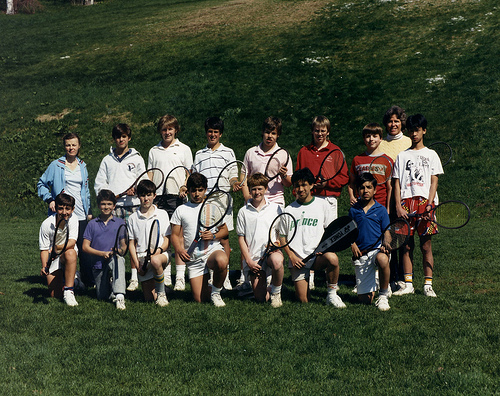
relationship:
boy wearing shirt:
[86, 188, 131, 310] [87, 215, 129, 248]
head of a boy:
[136, 179, 157, 208] [124, 178, 172, 306]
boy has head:
[258, 100, 286, 165] [259, 113, 283, 149]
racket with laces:
[251, 213, 297, 278] [209, 206, 219, 216]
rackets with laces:
[177, 160, 249, 261] [209, 206, 219, 216]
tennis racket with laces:
[48, 211, 68, 272] [209, 206, 219, 216]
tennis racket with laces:
[315, 147, 347, 184] [209, 206, 219, 216]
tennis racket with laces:
[264, 142, 289, 179] [209, 206, 219, 216]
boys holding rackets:
[36, 112, 446, 309] [177, 158, 244, 263]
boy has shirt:
[344, 171, 395, 313] [345, 199, 393, 254]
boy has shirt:
[292, 117, 343, 219] [293, 141, 348, 189]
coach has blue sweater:
[25, 120, 99, 237] [34, 155, 94, 215]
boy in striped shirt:
[196, 117, 236, 215] [193, 143, 238, 187]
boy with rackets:
[196, 117, 236, 215] [177, 160, 249, 261]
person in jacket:
[35, 131, 90, 291] [36, 156, 91, 218]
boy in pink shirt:
[239, 117, 294, 206] [227, 119, 297, 189]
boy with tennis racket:
[239, 117, 294, 206] [243, 143, 305, 205]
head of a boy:
[55, 193, 76, 220] [38, 193, 79, 307]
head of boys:
[174, 171, 210, 202] [168, 171, 229, 309]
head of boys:
[186, 172, 209, 203] [168, 171, 229, 309]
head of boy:
[284, 163, 324, 206] [279, 167, 347, 309]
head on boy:
[157, 114, 180, 139] [140, 116, 195, 202]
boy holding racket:
[409, 116, 431, 214] [270, 218, 301, 249]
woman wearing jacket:
[35, 131, 97, 297] [34, 152, 92, 217]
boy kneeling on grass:
[125, 179, 169, 304] [1, 0, 497, 394]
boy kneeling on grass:
[82, 189, 129, 311] [1, 0, 497, 394]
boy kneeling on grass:
[38, 192, 78, 307] [1, 0, 497, 394]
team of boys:
[35, 100, 446, 314] [36, 112, 446, 309]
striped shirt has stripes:
[192, 146, 238, 191] [195, 151, 230, 173]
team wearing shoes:
[35, 100, 446, 314] [320, 286, 347, 311]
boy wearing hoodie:
[94, 122, 150, 222] [91, 143, 149, 203]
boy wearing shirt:
[392, 114, 444, 298] [383, 133, 437, 212]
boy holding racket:
[392, 114, 444, 298] [236, 205, 327, 258]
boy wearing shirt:
[38, 193, 79, 307] [35, 205, 78, 256]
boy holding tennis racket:
[38, 193, 79, 307] [42, 212, 74, 274]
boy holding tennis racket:
[89, 118, 151, 210] [117, 163, 166, 200]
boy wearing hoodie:
[89, 118, 151, 210] [94, 147, 144, 193]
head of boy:
[94, 191, 120, 213] [82, 189, 129, 311]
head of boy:
[403, 114, 427, 142] [392, 114, 444, 298]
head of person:
[186, 172, 209, 203] [167, 170, 229, 310]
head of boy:
[311, 114, 329, 144] [292, 114, 349, 217]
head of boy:
[109, 120, 134, 148] [91, 110, 150, 286]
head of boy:
[399, 114, 427, 144] [389, 113, 444, 299]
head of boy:
[354, 174, 378, 202] [344, 171, 395, 313]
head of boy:
[290, 169, 313, 199] [277, 166, 348, 308]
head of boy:
[130, 177, 158, 211] [124, 179, 173, 307]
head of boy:
[51, 191, 76, 223] [32, 193, 87, 310]